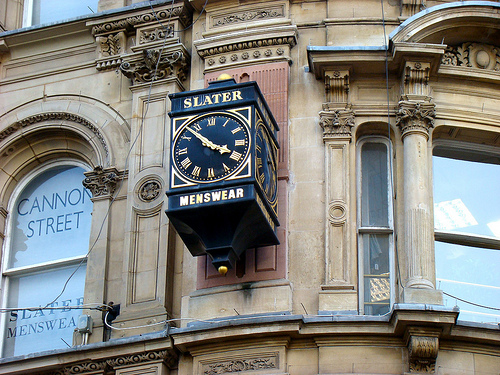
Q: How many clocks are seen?
A: One.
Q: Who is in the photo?
A: No one.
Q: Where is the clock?
A: On the building.